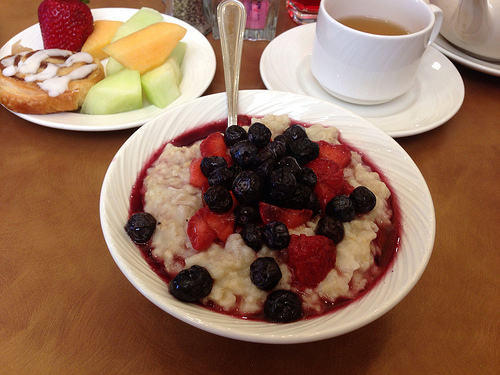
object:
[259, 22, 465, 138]
plate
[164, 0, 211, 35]
shaker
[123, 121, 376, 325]
fruit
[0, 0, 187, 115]
fresh fruit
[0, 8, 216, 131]
plate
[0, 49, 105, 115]
danish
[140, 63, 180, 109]
cantaloupe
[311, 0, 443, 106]
cup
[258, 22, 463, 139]
saucer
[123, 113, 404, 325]
oatmeal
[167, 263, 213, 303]
blueberries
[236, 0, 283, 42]
sugar holder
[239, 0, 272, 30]
pink packets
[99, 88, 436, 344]
bowl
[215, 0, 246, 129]
handle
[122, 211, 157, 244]
blueberries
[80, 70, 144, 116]
honey dew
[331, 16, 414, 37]
tea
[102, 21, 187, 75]
cantaloupe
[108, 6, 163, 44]
cantaloupe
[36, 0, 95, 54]
strawberry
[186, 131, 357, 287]
strawberries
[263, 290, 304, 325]
blueberries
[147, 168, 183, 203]
oatmeal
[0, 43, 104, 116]
pastry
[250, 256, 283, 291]
blueberry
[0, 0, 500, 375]
photograph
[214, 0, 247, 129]
flat ware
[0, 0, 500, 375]
table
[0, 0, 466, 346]
breakfast